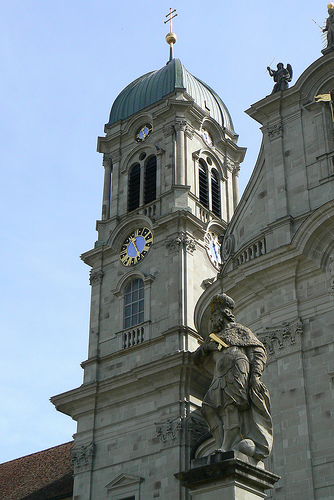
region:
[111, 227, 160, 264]
a black and gold clock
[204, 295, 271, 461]
a gray stone statue of a man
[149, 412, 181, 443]
fanc stone carving on building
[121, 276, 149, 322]
an arched window in a building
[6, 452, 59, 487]
brown terra cotta shingles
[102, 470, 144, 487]
a triangle above a window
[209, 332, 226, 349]
a golden sword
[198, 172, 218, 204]
black shutters on a window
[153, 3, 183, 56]
a metal weather vane on the roof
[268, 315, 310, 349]
stone carvings on the wall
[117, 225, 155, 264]
gold clock with blue center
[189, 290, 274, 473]
gray statue with bit of gold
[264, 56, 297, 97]
statue of angel holding something gold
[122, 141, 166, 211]
two windows with black shades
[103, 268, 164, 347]
window divided up with grilles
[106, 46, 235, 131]
blue dome roof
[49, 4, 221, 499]
gray tower with multiple clocks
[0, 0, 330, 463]
clear light blue sky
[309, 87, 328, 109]
small gold flag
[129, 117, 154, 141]
clock, black with blue center, gold hands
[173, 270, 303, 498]
a statue on a pole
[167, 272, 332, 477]
a statue high in the air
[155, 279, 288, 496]
a cement statue high in the air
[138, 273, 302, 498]
a statue made of cement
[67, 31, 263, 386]
a building with a clock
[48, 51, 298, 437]
a building with an outside clock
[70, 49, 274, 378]
a clock on a building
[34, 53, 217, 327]
a clock on the outside of a building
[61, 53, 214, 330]
a tall building with a clock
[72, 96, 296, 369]
an old building with a clock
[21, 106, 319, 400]
a clock on the outside of a building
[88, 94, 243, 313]
an outside clock on a building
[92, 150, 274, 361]
an outside clock on the outside of a building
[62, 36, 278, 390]
a clock on a tall building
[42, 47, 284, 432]
an outside clock on a tall building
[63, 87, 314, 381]
a clock on an old building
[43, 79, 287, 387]
an outside clock on an old building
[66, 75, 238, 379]
a tall buidling with a clock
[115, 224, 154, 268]
it is 11:27 AM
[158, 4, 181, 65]
this cross indicates a christian cathedral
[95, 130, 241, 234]
the church bells are located here in the tower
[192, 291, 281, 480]
this statue may represent a patron saint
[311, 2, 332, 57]
this stature has metal strands added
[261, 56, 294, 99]
this stature represents an angel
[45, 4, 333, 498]
the cathedral is gothic style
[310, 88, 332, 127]
this flag is likely part of an unseen statue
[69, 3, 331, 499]
the cathedral appears to be built primarily with grannet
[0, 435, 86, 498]
this rooftop may not be part of the cathedral